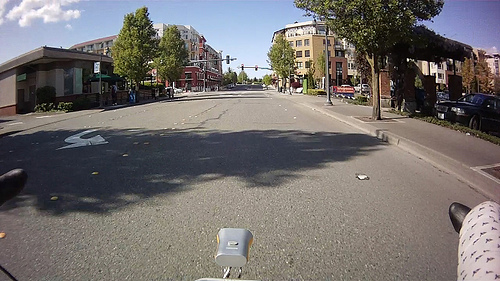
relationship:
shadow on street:
[1, 131, 388, 212] [4, 90, 494, 277]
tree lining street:
[112, 4, 162, 103] [4, 90, 494, 277]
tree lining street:
[158, 23, 191, 87] [4, 90, 494, 277]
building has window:
[284, 34, 337, 86] [304, 39, 313, 48]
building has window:
[284, 34, 337, 86] [295, 49, 304, 58]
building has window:
[284, 34, 337, 86] [294, 39, 303, 48]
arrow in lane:
[56, 126, 109, 151] [2, 94, 232, 233]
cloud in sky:
[0, 0, 84, 34] [2, 2, 499, 76]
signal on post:
[241, 62, 246, 71] [236, 65, 274, 72]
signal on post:
[253, 64, 260, 72] [236, 65, 274, 72]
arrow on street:
[56, 126, 109, 151] [4, 90, 494, 277]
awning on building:
[94, 72, 112, 81] [0, 43, 131, 115]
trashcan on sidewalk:
[129, 89, 138, 105] [0, 94, 191, 136]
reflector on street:
[51, 195, 59, 202] [4, 90, 494, 277]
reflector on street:
[91, 168, 100, 177] [4, 90, 494, 277]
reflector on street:
[159, 132, 167, 138] [4, 90, 494, 277]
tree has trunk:
[291, 0, 445, 119] [366, 55, 383, 120]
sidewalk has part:
[287, 91, 499, 201] [472, 160, 500, 182]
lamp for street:
[313, 21, 333, 109] [4, 90, 494, 277]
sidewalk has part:
[287, 91, 499, 201] [328, 104, 375, 117]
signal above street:
[241, 62, 246, 71] [4, 90, 494, 277]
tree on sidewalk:
[291, 0, 445, 119] [287, 91, 499, 201]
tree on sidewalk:
[112, 4, 162, 103] [0, 94, 191, 136]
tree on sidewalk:
[158, 23, 191, 87] [0, 94, 191, 136]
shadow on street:
[171, 94, 267, 101] [4, 90, 494, 277]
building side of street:
[162, 66, 223, 90] [4, 90, 494, 277]